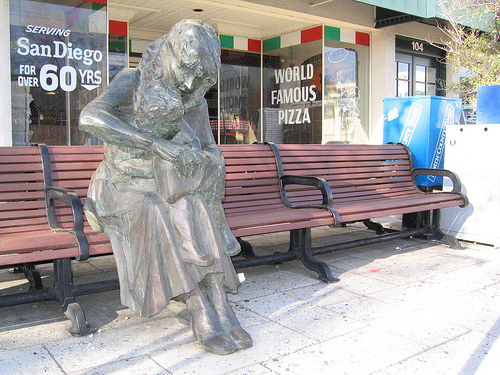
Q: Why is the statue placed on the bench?
A: To attract people.